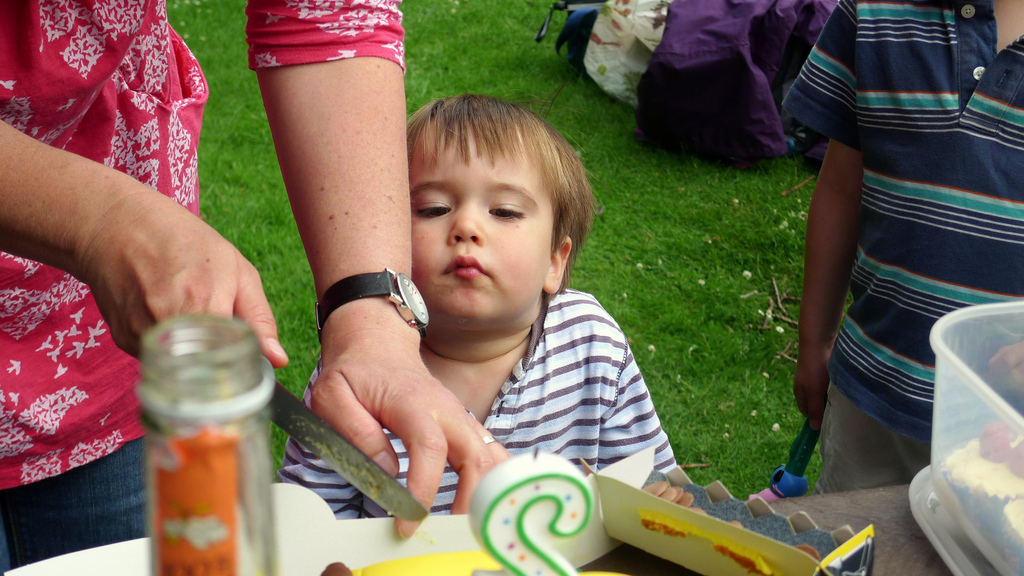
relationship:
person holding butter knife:
[0, 0, 515, 572] [269, 381, 430, 520]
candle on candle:
[473, 450, 604, 576] [473, 457, 609, 574]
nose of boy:
[451, 205, 480, 237] [264, 84, 689, 508]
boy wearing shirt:
[280, 93, 699, 526] [428, 345, 671, 480]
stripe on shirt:
[533, 357, 629, 377] [428, 345, 671, 480]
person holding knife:
[4, 3, 517, 539] [293, 401, 428, 523]